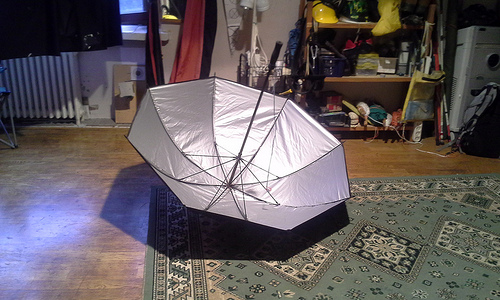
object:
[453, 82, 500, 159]
backpack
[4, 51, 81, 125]
radiator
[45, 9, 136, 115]
wall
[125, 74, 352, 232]
umbrella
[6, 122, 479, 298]
floor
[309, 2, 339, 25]
safety helmet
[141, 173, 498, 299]
area rug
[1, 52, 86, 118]
wall furnace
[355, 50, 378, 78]
boxes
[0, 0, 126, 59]
curtain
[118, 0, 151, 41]
window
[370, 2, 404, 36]
shopping bag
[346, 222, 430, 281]
diamond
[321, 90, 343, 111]
box